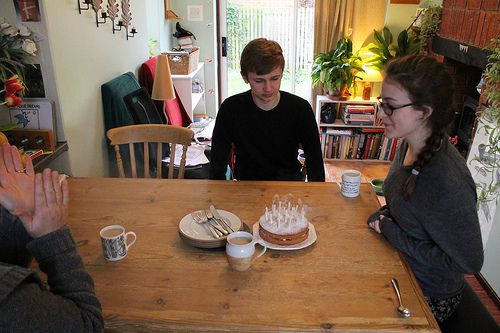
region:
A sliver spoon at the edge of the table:
[386, 275, 411, 318]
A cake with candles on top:
[250, 198, 319, 255]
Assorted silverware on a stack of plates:
[189, 205, 234, 237]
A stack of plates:
[170, 204, 242, 251]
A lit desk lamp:
[353, 60, 383, 103]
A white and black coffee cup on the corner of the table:
[328, 166, 363, 198]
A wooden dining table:
[63, 171, 440, 331]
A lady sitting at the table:
[368, 50, 486, 324]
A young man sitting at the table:
[204, 29, 328, 183]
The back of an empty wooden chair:
[102, 120, 196, 178]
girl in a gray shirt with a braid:
[363, 56, 482, 318]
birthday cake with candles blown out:
[260, 205, 307, 245]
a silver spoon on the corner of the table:
[389, 278, 411, 318]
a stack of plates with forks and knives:
[177, 203, 238, 248]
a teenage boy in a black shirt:
[209, 42, 326, 178]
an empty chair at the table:
[107, 123, 193, 179]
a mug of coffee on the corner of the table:
[332, 168, 362, 200]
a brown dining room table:
[45, 177, 441, 332]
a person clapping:
[1, 135, 108, 332]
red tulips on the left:
[1, 70, 22, 112]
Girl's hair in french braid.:
[380, 56, 457, 198]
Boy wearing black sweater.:
[209, 36, 330, 187]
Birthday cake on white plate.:
[250, 197, 317, 252]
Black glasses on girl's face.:
[375, 89, 415, 116]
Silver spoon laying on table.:
[389, 274, 412, 323]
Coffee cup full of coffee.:
[97, 224, 137, 259]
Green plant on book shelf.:
[312, 40, 353, 100]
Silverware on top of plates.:
[172, 205, 243, 252]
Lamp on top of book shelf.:
[357, 54, 382, 100]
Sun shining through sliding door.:
[227, 0, 316, 100]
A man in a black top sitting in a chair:
[215, 36, 326, 177]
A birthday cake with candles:
[247, 193, 323, 251]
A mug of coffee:
[95, 223, 141, 263]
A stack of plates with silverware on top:
[177, 195, 242, 250]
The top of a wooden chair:
[105, 123, 195, 176]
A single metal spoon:
[383, 270, 415, 325]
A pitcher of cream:
[220, 226, 270, 278]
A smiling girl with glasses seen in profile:
[372, 48, 458, 147]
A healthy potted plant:
[313, 38, 357, 99]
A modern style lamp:
[147, 54, 182, 121]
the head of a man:
[233, 25, 334, 108]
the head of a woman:
[363, 59, 459, 144]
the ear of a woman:
[411, 88, 456, 128]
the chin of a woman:
[376, 120, 420, 150]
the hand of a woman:
[351, 189, 423, 257]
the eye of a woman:
[379, 94, 410, 120]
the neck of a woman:
[391, 83, 463, 161]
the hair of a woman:
[362, 48, 482, 202]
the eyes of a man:
[239, 66, 290, 102]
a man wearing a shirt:
[194, 51, 334, 218]